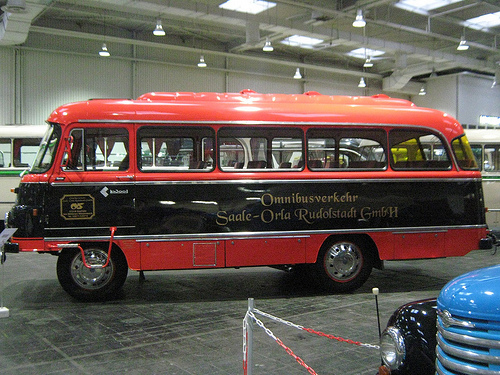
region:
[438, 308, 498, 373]
sky blue hood on truck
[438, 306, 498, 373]
sky blue and silver grill on truck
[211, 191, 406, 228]
name of service printed on side of bus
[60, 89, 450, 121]
red shiny hood on mini bus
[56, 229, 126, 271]
red and silver foot lifter on driver side of mini bus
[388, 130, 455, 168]
rear side window on right side of mini bus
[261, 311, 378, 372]
red and white chain surrounding antiquated vehicle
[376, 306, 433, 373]
front head light surrounded by black painted hood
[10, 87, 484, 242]
black and red mini bus parked in garage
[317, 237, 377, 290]
rear wheel on right side of mini bus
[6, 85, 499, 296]
red tour bus with black stripe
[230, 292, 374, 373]
red and white chain link rope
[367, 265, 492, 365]
front of a light blue truck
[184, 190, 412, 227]
german words on the side of a bus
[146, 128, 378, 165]
passenger windows on the side of a bus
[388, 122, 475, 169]
yellow tinted windows on the side of a bus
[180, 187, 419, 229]
words written in fancy font on the side of a bus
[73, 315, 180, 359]
dusty linoleum floor in a car museum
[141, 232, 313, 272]
opening under the bus for luggage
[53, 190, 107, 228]
medallion on the side of the bus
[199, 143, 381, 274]
A bus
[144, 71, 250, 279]
A bus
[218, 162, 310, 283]
A bus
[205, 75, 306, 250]
A bus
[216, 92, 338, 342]
A bus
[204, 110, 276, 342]
A bus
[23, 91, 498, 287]
a red and black bus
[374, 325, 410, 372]
a headlight on a vehicle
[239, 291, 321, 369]
a red and white chain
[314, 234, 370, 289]
a wheel on a vehicle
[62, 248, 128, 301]
a wheel on a vehicle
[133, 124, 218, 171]
a window on a bus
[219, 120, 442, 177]
the windows on a bus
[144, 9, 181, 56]
a light on a cieling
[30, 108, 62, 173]
front window of a bus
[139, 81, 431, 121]
the roof of a bus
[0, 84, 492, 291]
A bus once used for public transportation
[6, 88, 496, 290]
a black and red public trasit bus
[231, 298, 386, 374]
a red and white chain to keep spectators back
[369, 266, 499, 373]
a bright blue vehicle with navy fender and chrome accents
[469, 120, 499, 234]
portion of cream colored bus with green pin stripe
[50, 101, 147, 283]
entrance door to bus with a step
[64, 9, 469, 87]
suspended lights from the ceiling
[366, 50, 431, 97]
portion of ductwork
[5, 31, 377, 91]
pipes of building exposed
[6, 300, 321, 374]
dust covered black floor